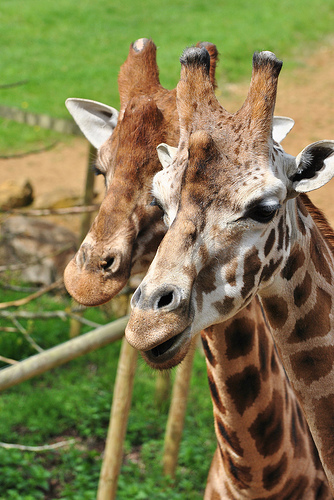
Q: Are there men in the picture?
A: No, there are no men.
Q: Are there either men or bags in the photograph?
A: No, there are no men or bags.